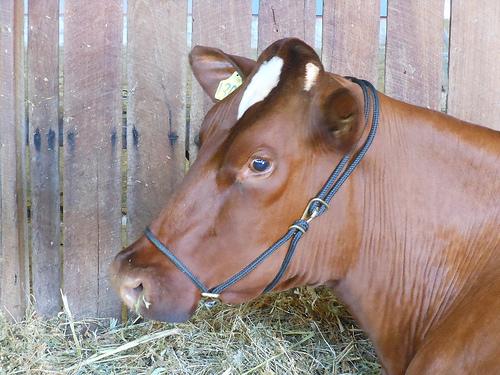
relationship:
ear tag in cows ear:
[214, 71, 244, 101] [188, 29, 254, 92]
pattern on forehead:
[237, 57, 284, 120] [228, 37, 295, 118]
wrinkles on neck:
[294, 187, 493, 346] [349, 82, 489, 372]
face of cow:
[112, 38, 362, 322] [111, 35, 498, 372]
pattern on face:
[231, 54, 286, 126] [112, 38, 362, 322]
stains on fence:
[29, 122, 189, 157] [4, 8, 173, 243]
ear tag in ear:
[214, 71, 244, 101] [186, 44, 258, 104]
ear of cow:
[186, 44, 258, 104] [111, 35, 498, 372]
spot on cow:
[227, 56, 289, 125] [134, 27, 429, 374]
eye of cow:
[247, 154, 272, 172] [111, 35, 498, 372]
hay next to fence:
[0, 288, 350, 374] [5, 10, 108, 325]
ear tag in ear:
[214, 71, 244, 101] [185, 38, 249, 110]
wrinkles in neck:
[359, 145, 493, 346] [349, 82, 489, 372]